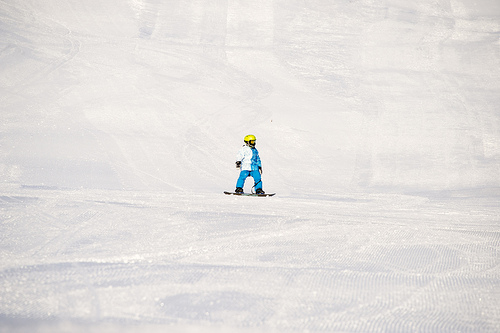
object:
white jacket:
[237, 145, 261, 171]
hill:
[0, 0, 499, 333]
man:
[234, 133, 266, 194]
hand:
[258, 166, 263, 174]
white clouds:
[251, 174, 404, 207]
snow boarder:
[373, 133, 500, 210]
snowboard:
[223, 191, 276, 197]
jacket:
[235, 146, 262, 174]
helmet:
[244, 135, 256, 147]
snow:
[0, 34, 499, 332]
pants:
[236, 170, 263, 190]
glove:
[236, 160, 242, 168]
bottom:
[0, 180, 181, 256]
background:
[102, 100, 454, 227]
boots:
[256, 188, 265, 193]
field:
[12, 50, 454, 287]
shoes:
[235, 187, 244, 192]